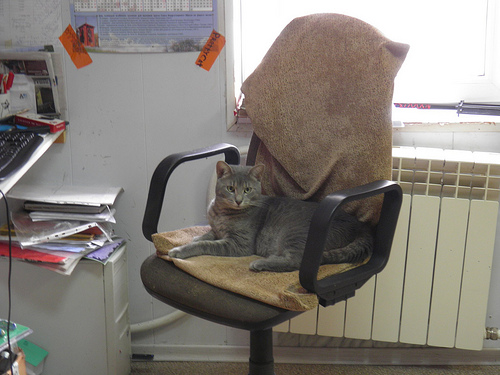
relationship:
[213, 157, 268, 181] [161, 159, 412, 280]
ears of cat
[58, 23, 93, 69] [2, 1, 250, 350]
tape on wall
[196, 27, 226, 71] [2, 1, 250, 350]
tape on wall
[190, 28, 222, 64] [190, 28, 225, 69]
writing on tape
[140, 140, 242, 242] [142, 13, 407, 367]
arm rest of chair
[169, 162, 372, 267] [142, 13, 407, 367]
cat laying on chair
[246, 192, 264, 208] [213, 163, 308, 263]
whiskes on cat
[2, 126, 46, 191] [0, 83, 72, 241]
keyboard on desk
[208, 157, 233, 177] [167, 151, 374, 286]
ear of a cat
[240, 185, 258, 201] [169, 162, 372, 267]
eye of a cat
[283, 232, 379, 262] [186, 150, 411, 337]
tail of a cat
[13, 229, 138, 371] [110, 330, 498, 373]
unit on floor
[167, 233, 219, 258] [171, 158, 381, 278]
front paws on a cat